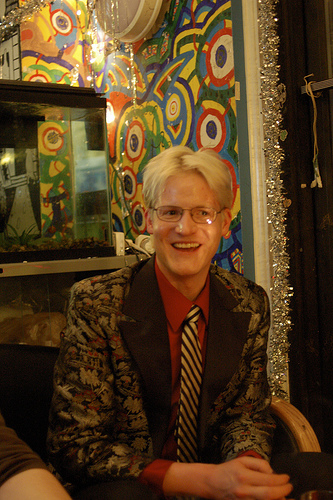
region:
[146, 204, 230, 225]
man is wearing glasses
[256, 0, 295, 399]
tinsel hanging along door frame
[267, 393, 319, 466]
curved wooden arm of chair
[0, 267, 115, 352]
fish tank in background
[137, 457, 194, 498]
cuff of red shirt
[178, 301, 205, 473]
black and white striped tie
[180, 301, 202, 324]
tie is knotted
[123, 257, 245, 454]
dark lapels on jacket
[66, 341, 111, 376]
hut design on jacket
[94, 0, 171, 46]
clock hanging on wall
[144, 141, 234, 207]
Man had blonde hair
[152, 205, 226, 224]
Man wearing eyeglasses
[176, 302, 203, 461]
Man wearing striped tie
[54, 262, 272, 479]
Man wearing flowered jacket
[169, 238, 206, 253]
Man has big smile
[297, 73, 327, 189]
String hanging from pole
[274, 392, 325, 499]
Arm of chair is wood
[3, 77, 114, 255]
Aquarium on table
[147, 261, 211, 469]
Man wearing red shirt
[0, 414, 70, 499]
Arm of an unknown person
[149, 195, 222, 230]
man wearing wired framed glasses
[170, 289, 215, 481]
man wearing a black and yellow tie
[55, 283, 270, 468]
man wearing a floral suit jacket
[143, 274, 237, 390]
man wearing a red shirt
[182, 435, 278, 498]
man hand placed on top of his other hand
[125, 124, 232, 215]
man with blonde hair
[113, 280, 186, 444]
brown collar on a suit jacket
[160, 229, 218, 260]
man with his mouth open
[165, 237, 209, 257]
man with a smile on his face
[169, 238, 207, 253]
man with white teeth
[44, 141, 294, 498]
older man with fluffy white hair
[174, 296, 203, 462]
black and grey diagonally striped tie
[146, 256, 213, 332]
dark red shirt collar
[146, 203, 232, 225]
rectangular wire framed glasses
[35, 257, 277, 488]
jacket with a bizarre print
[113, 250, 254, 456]
large black lapel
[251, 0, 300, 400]
silver glittery length of garland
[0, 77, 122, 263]
big fish tank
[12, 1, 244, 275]
brightly coloured and patterned wall mural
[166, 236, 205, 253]
smile of straight white teeth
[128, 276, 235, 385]
this is a man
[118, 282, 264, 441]
the man is elderly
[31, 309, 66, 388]
this is a jacket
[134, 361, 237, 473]
this is a tie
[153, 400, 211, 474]
the tie is striped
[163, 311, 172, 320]
this is a collar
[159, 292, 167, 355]
the collar is red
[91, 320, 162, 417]
the lapel is black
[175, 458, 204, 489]
this is a wrist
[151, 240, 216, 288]
this is a chin